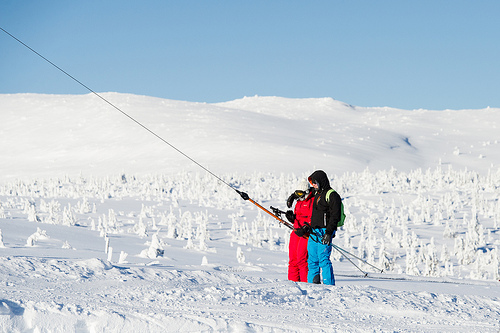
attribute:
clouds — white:
[241, 32, 421, 122]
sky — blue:
[12, 6, 499, 156]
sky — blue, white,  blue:
[1, 0, 498, 107]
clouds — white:
[418, 44, 480, 77]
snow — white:
[3, 91, 498, 331]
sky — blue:
[380, 42, 434, 59]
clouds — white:
[3, 1, 499, 106]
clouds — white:
[59, 52, 499, 89]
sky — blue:
[311, 14, 376, 92]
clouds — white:
[18, 21, 67, 79]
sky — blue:
[393, 31, 455, 63]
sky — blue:
[175, 22, 255, 97]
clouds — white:
[233, 50, 291, 147]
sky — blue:
[130, 55, 280, 138]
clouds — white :
[109, 50, 197, 128]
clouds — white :
[87, 50, 222, 120]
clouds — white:
[106, 51, 237, 149]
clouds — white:
[94, 50, 244, 60]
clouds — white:
[231, 19, 377, 89]